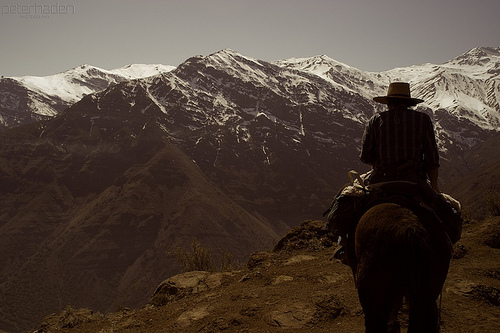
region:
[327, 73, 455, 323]
man on a horse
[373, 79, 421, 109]
hat on mans head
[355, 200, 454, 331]
rear end of horse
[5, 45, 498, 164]
snow caps on mountains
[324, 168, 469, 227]
saddle on back of horse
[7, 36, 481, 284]
mountains in distance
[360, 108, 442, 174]
stripped short on man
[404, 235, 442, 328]
horses long tail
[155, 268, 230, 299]
rock on side of cliff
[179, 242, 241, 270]
grass on side of cliff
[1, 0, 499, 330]
Cowboy scene in sepia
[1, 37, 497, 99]
Snow capped mountains in the background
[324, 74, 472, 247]
Man wearing a cowboy hat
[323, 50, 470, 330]
Man riding a horse in the mountains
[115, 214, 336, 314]
The edge of a rocky terrain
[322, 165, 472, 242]
Saddle bags on the back of the horse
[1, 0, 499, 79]
The sky is clear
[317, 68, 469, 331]
Silhouette of a man riding a horse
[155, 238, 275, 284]
Brush by the rocks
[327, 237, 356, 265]
Man's foot in a stirrup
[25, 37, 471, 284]
Man on horseback overlooking mountains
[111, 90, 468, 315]
Man on horse at the edge of a cliff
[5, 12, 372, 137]
Mountains with snow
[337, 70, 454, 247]
Man with a hat on a horse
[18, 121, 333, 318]
Mountains near a cliff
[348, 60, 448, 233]
Man on horse with a checkered shirt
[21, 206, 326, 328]
Rocks at the edge of a cliff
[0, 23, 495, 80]
Snow on the top of mountains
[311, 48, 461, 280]
Back of a man on horse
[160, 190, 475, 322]
Horse's hind parts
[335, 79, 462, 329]
cowboy on horse back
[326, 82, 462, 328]
man riding a horse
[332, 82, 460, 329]
cowboy riding a horse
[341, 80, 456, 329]
person riding a horse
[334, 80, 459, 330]
guy riding a horse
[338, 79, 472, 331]
man in a ten gallon hat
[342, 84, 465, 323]
cowboy in a ten gallon hat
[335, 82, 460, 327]
person in a ten gallon hat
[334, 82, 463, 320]
guy in a ten gallon hat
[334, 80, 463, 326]
man looking at the mountains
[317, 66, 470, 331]
person riding horse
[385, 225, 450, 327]
horse tail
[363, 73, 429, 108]
hat on person riding horse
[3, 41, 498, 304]
snow covered mountains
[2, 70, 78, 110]
white snow on top of mountain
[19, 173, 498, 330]
top od brown mountain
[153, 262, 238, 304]
brown rock on side of mountain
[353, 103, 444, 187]
long sleeve shirt with plaid design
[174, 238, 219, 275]
green plant on side of rock on mountain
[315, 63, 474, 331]
back of person riding horse